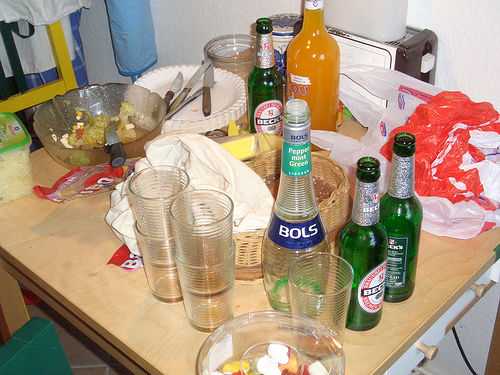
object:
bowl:
[191, 309, 342, 375]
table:
[0, 110, 500, 374]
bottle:
[260, 98, 332, 318]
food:
[305, 360, 331, 375]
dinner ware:
[161, 55, 216, 120]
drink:
[284, 0, 343, 154]